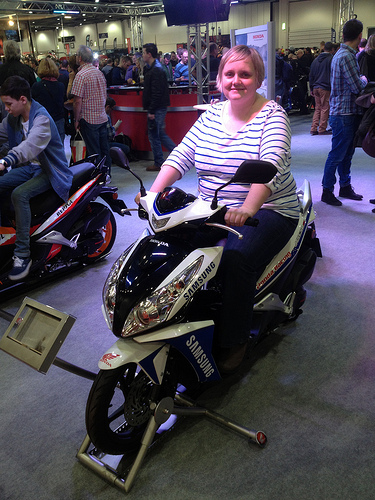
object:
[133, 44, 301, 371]
woman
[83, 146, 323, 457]
vehicle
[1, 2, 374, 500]
convention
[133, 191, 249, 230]
hands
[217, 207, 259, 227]
handlebars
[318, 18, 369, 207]
man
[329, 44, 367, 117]
shirt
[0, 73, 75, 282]
boy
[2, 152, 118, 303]
scooter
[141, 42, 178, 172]
man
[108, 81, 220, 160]
partition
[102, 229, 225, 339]
panel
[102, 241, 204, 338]
headlights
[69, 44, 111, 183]
man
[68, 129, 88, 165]
bag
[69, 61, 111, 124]
shirt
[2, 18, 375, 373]
people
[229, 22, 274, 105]
sign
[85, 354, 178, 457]
wheel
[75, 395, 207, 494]
lock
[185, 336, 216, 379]
logo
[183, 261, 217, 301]
logo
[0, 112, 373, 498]
floor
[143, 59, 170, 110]
jacket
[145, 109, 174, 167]
jeans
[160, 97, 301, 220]
shirt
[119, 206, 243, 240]
break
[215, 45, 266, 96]
hair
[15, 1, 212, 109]
railing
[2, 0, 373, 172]
background